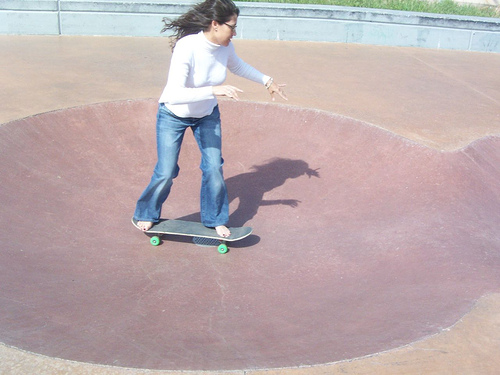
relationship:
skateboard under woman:
[131, 217, 253, 254] [133, 0, 288, 237]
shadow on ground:
[144, 158, 321, 247] [0, 34, 499, 375]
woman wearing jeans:
[133, 0, 288, 237] [133, 104, 229, 229]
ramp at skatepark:
[1, 97, 500, 373] [1, 1, 499, 374]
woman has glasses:
[133, 0, 288, 237] [223, 22, 236, 32]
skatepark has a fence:
[1, 1, 499, 374] [0, 0, 499, 53]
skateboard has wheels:
[131, 217, 253, 254] [150, 236, 227, 254]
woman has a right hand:
[133, 0, 288, 237] [214, 86, 243, 101]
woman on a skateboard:
[133, 0, 288, 237] [131, 217, 253, 254]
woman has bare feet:
[133, 0, 288, 237] [136, 220, 231, 239]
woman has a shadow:
[133, 0, 288, 237] [144, 158, 321, 247]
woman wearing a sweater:
[133, 0, 288, 237] [158, 30, 271, 118]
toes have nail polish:
[137, 222, 230, 238] [143, 226, 225, 237]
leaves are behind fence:
[236, 0, 496, 19] [0, 0, 499, 53]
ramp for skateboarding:
[1, 97, 500, 373] [133, 0, 288, 237]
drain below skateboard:
[193, 236, 223, 248] [131, 217, 253, 254]